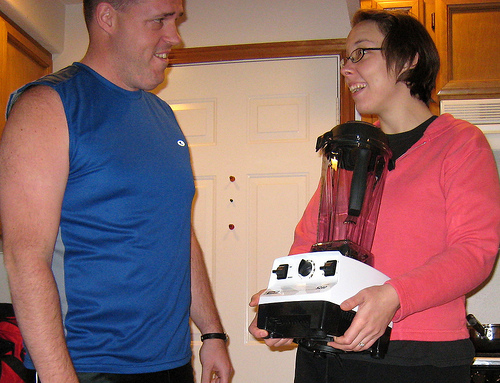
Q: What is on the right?
A: Person in a pink shirt.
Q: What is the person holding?
A: A blender.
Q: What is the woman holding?
A: Kitchen appliance.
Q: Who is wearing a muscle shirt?
A: The man.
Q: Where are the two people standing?
A: In a kitchen.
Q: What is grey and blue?
A: Muscle shirt.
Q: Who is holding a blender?
A: Woman in pink.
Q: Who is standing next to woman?
A: The man.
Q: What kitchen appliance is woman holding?
A: A blender.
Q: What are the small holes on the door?
A: Peepholes.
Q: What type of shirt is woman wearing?
A: Sweatshirt.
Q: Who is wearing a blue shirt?
A: The man.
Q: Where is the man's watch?
A: On left wrist.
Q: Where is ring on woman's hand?
A: On left hand.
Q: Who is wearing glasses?
A: The woman.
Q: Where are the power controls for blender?
A: On the base.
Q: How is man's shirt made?
A: Shirt is sleeveless.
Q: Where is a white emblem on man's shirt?
A: Left side at top.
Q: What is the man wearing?
A: A blue shirt.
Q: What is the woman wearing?
A: A red sweater.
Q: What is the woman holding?
A: An electric blender.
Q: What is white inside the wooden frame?
A: A door.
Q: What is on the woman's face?
A: Eyeglasses.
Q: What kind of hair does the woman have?
A: Short and brown.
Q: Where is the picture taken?
A: Kitchen.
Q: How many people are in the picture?
A: Two.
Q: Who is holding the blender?
A: A woman.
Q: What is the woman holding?
A: Blender.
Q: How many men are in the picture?
A: One.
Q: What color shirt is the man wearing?
A: Blue.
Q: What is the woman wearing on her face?
A: Glasses.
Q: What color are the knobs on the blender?
A: Black.